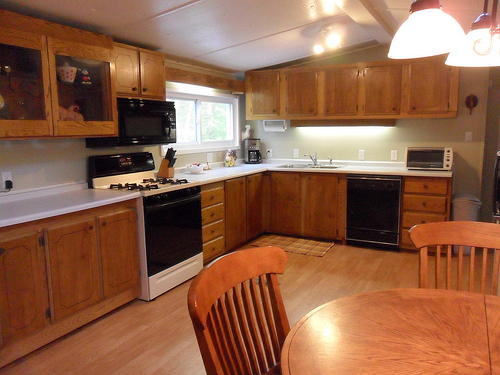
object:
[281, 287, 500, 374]
table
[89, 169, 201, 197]
cooktop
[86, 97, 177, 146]
microwave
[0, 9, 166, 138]
cabinets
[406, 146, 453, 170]
oven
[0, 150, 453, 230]
counter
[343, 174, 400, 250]
dishwasher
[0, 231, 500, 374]
floor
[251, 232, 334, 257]
rug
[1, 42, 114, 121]
windows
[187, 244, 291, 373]
chair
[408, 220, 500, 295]
chair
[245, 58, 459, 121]
cabinets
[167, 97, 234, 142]
window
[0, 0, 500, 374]
kitchen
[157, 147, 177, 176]
knives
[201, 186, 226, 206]
drawer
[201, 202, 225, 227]
drawer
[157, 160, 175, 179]
block